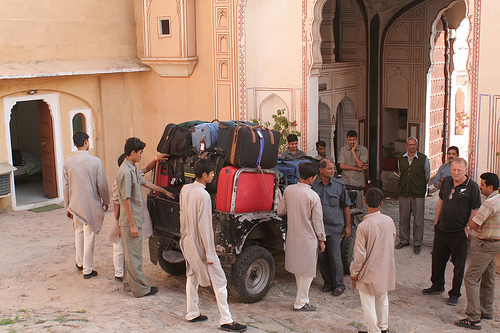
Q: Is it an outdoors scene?
A: Yes, it is outdoors.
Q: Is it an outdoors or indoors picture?
A: It is outdoors.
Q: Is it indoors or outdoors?
A: It is outdoors.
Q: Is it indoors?
A: No, it is outdoors.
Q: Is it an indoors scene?
A: No, it is outdoors.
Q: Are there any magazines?
A: No, there are no magazines.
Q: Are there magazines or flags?
A: No, there are no magazines or flags.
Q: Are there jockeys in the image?
A: No, there are no jockeys.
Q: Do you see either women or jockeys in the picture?
A: No, there are no jockeys or women.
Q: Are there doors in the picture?
A: Yes, there is a door.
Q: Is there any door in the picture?
A: Yes, there is a door.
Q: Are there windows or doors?
A: Yes, there is a door.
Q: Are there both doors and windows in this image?
A: Yes, there are both a door and windows.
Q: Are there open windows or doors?
A: Yes, there is an open door.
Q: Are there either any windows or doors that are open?
A: Yes, the door is open.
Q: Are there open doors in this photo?
A: Yes, there is an open door.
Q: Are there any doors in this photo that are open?
A: Yes, there is a door that is open.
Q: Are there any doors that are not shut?
A: Yes, there is a open door.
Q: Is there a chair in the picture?
A: No, there are no chairs.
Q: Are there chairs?
A: No, there are no chairs.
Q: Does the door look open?
A: Yes, the door is open.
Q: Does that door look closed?
A: No, the door is open.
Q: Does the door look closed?
A: No, the door is open.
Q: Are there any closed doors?
A: No, there is a door but it is open.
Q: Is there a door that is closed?
A: No, there is a door but it is open.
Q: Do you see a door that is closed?
A: No, there is a door but it is open.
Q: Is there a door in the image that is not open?
A: No, there is a door but it is open.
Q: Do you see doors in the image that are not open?
A: No, there is a door but it is open.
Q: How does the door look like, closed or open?
A: The door is open.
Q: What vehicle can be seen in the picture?
A: The vehicle is a jeep.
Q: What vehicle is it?
A: The vehicle is a jeep.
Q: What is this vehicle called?
A: This is a jeep.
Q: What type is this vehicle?
A: This is a jeep.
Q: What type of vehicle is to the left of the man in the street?
A: The vehicle is a jeep.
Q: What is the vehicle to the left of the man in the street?
A: The vehicle is a jeep.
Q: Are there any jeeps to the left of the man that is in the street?
A: Yes, there is a jeep to the left of the man.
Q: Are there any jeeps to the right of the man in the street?
A: No, the jeep is to the left of the man.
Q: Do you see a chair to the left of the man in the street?
A: No, there is a jeep to the left of the man.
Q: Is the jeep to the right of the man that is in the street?
A: No, the jeep is to the left of the man.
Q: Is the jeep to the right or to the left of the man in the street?
A: The jeep is to the left of the man.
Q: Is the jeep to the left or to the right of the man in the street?
A: The jeep is to the left of the man.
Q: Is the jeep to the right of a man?
A: Yes, the jeep is to the right of a man.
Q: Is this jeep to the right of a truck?
A: No, the jeep is to the right of a man.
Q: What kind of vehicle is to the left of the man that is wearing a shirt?
A: The vehicle is a jeep.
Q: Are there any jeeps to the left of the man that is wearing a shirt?
A: Yes, there is a jeep to the left of the man.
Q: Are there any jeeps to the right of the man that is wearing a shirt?
A: No, the jeep is to the left of the man.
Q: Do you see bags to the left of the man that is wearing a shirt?
A: No, there is a jeep to the left of the man.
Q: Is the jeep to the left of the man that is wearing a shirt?
A: Yes, the jeep is to the left of the man.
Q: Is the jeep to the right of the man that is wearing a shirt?
A: No, the jeep is to the left of the man.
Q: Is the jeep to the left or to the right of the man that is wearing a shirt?
A: The jeep is to the left of the man.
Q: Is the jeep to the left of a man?
A: Yes, the jeep is to the left of a man.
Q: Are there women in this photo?
A: No, there are no women.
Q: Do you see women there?
A: No, there are no women.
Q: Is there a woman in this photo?
A: No, there are no women.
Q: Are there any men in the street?
A: Yes, there is a man in the street.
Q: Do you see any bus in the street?
A: No, there is a man in the street.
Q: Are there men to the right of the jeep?
A: Yes, there is a man to the right of the jeep.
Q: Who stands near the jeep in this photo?
A: The man stands near the jeep.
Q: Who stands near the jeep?
A: The man stands near the jeep.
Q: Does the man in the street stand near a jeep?
A: Yes, the man stands near a jeep.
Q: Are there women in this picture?
A: No, there are no women.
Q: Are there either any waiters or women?
A: No, there are no women or waiters.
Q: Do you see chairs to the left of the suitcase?
A: No, there is a man to the left of the suitcase.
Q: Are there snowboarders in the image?
A: No, there are no snowboarders.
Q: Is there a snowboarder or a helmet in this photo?
A: No, there are no snowboarders or helmets.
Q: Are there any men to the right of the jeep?
A: Yes, there is a man to the right of the jeep.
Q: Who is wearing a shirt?
A: The man is wearing a shirt.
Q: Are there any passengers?
A: No, there are no passengers.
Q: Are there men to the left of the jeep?
A: Yes, there is a man to the left of the jeep.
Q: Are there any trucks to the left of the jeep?
A: No, there is a man to the left of the jeep.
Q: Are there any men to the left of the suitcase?
A: Yes, there is a man to the left of the suitcase.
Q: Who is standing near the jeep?
A: The man is standing near the jeep.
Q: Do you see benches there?
A: No, there are no benches.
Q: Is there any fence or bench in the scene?
A: No, there are no benches or fences.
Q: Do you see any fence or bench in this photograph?
A: No, there are no benches or fences.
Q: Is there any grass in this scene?
A: Yes, there is grass.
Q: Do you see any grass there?
A: Yes, there is grass.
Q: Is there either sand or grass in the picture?
A: Yes, there is grass.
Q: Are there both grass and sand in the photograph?
A: No, there is grass but no sand.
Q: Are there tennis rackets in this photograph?
A: No, there are no tennis rackets.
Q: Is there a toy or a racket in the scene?
A: No, there are no rackets or toys.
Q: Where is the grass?
A: The grass is on the ground.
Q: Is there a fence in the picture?
A: No, there are no fences.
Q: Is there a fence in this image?
A: No, there are no fences.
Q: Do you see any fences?
A: No, there are no fences.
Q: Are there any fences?
A: No, there are no fences.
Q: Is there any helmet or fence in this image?
A: No, there are no fences or helmets.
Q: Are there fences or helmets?
A: No, there are no fences or helmets.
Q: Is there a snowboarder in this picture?
A: No, there are no snowboarders.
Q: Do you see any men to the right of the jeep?
A: Yes, there is a man to the right of the jeep.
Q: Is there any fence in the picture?
A: No, there are no fences.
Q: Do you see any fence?
A: No, there are no fences.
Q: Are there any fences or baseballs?
A: No, there are no fences or baseballs.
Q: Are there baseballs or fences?
A: No, there are no fences or baseballs.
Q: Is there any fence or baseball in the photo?
A: No, there are no fences or baseballs.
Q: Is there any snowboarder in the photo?
A: No, there are no snowboarders.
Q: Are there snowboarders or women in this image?
A: No, there are no snowboarders or women.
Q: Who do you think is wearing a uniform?
A: The man is wearing a uniform.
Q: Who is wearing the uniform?
A: The man is wearing a uniform.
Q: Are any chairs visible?
A: No, there are no chairs.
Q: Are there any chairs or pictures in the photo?
A: No, there are no chairs or pictures.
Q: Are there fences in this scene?
A: No, there are no fences.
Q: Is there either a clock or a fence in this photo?
A: No, there are no fences or clocks.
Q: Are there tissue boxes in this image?
A: No, there are no tissue boxes.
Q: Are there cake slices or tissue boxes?
A: No, there are no tissue boxes or cake slices.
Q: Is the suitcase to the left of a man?
A: No, the suitcase is to the right of a man.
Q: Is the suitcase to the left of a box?
A: No, the suitcase is to the left of a man.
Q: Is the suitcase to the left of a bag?
A: No, the suitcase is to the left of a man.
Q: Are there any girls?
A: No, there are no girls.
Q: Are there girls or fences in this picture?
A: No, there are no girls or fences.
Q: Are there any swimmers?
A: No, there are no swimmers.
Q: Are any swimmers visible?
A: No, there are no swimmers.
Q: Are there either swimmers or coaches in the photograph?
A: No, there are no swimmers or coaches.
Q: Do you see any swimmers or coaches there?
A: No, there are no swimmers or coaches.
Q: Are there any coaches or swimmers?
A: No, there are no swimmers or coaches.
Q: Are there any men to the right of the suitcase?
A: Yes, there is a man to the right of the suitcase.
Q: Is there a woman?
A: No, there are no women.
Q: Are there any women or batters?
A: No, there are no women or batters.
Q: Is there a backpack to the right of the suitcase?
A: No, there is a man to the right of the suitcase.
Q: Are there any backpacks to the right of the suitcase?
A: No, there is a man to the right of the suitcase.